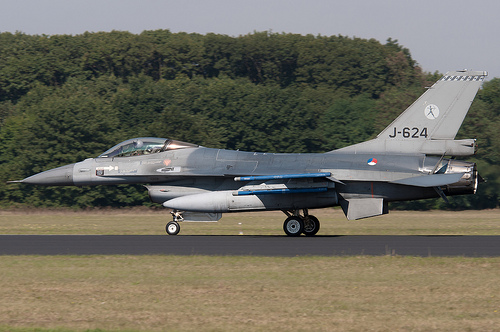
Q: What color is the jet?
A: Grey.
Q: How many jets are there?
A: 1.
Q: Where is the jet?
A: On the runway.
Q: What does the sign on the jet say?
A: J-624.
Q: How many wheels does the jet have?
A: 3.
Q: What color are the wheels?
A: Black and white.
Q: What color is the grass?
A: Yellow.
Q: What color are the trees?
A: Green.